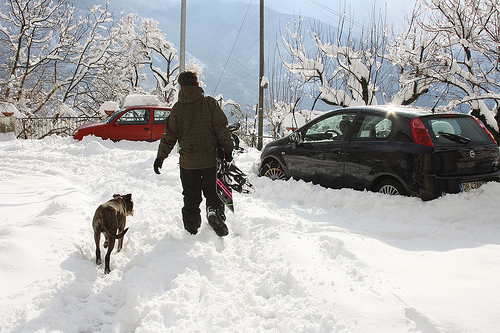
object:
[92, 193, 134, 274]
dog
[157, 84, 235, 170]
jacket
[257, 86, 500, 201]
car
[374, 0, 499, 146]
trees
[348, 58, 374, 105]
snow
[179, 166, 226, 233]
pants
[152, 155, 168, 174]
glove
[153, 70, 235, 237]
man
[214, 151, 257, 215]
snowboard